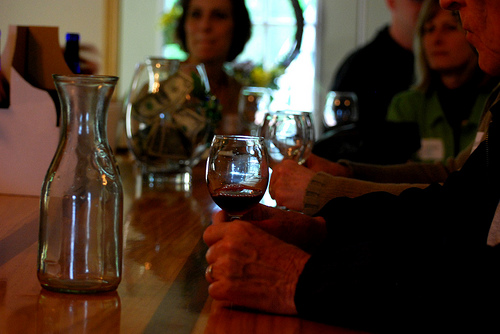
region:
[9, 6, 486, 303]
these people are having a celebration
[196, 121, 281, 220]
wine in a glass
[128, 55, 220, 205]
money in a dish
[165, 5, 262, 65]
this lady is looking content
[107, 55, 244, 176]
dollars in a glass jar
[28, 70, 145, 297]
an empty glass vase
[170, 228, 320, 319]
this man's hand is wrinkled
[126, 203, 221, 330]
the table has a dark striped piece of wood\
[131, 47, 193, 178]
money displayed in a vase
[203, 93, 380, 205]
people holding wine glasses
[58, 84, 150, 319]
an empty pitcher sitting on a table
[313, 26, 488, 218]
people sitting at a table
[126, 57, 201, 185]
a money jar sitting on a table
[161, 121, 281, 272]
a person holding a filled wine glass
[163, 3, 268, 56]
a woman sitting at the end of the table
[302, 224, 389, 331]
a man wearing a black shirt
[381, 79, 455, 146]
a woman wearing a green shirt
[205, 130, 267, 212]
clear glass on table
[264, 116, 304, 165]
clear glass on table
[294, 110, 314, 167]
clear glass on table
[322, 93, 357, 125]
clear glass on table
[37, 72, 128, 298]
clear pitcher on table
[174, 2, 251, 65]
woman with black hair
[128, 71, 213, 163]
dollar bills in bowl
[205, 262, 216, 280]
ring on man's finger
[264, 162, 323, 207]
hand holding wine glass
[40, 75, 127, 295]
Clear bottle on a counter top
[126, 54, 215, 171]
A jar full of money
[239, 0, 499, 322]
People sitting at a bar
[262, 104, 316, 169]
Glasses next to one another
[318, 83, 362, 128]
A wine glass in the background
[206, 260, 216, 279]
A ring on a man's hand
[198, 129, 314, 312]
A pair of hands on a glass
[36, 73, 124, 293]
A glass bottle on a wooden surface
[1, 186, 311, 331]
A glossy wooden surface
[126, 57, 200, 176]
clear jar with money in it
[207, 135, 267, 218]
glass with a small amount of red wine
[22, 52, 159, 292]
clear glass carafe on the counter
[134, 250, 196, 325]
counter top is wooden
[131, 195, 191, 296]
reflection in the counter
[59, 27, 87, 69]
top of a blue bottle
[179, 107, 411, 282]
people holding glasses of wine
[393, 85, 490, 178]
woman is wearing a green jacket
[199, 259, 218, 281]
man has on a wedding ring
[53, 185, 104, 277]
reflection in the glass